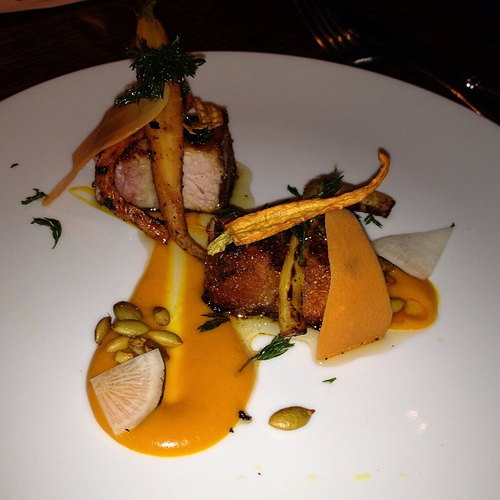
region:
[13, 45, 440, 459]
this is food in a plate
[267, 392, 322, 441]
this is a pumpkin seed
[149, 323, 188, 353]
this is a pumpkin seed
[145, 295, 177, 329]
this is a pumpkin seed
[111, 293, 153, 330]
this is a pumpkin seed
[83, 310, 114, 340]
this is a pumpkin seed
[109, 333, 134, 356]
this is a pumpkin seed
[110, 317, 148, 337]
this is a pumpkin seed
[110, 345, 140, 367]
this is a pumpkin seed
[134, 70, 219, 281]
this is a slice of carrot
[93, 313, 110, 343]
seed on the plate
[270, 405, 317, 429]
seed on the plate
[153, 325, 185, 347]
seed on the plate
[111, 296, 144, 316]
seed on the plate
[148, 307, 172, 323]
seed on the plate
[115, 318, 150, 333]
seed on the plate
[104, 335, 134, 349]
seed on the plate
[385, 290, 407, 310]
seed on the plate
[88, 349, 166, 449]
fruit on the plate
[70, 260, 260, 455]
sauce on a plate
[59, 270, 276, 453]
this is soup in a plate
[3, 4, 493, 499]
food on a plate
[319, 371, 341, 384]
speck of green on the plate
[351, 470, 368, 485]
speck of yellow on the plate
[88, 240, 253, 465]
thick mustard yellow sauce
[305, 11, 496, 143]
silver fork laying next to the plate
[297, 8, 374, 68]
tines on the fork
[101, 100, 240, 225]
hunk of meat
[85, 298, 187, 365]
seeds in the sauce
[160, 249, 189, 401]
smear line in the sauce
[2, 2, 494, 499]
a fancy dish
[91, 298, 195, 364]
possibly, these are pine nuts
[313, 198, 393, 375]
this appears to be a slice of mango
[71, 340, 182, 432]
a slice of some type of fruit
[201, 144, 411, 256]
some type of chili pepper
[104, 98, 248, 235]
a piece of some type of meat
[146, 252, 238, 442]
the sauce is orange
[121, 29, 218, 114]
possibly seaweed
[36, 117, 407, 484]
the plate is white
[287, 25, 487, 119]
utensils lay next to the plate